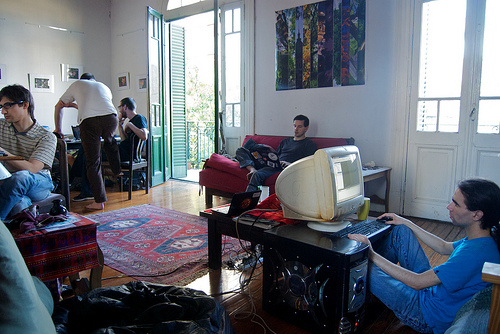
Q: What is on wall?
A: Picture.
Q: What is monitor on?
A: Wooden table.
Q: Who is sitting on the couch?
A: A man.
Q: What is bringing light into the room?
A: Windows and doors.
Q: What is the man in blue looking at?
A: A computer.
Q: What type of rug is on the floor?
A: An oriental rug.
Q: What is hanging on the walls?
A: Pictures.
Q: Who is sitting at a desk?
A: A man.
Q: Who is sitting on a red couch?
A: A man.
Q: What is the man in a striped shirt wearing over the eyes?
A: Glasses.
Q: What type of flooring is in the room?
A: Wood.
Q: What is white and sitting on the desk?
A: A computer.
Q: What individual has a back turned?
A: A man.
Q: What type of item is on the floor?
A: A rug.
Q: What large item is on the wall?
A: A poster.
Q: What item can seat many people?
A: A sofa.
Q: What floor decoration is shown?
A: A rug.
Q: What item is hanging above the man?
A: A picture.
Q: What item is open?
A: The door.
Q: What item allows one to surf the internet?
A: A computer.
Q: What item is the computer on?
A: A desk.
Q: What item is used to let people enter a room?
A: A door.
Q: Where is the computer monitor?
A: On table.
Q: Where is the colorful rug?
A: On floor.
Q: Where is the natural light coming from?
A: Windows.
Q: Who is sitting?
A: Man.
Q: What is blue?
A: Uniform.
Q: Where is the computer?
A: Desk.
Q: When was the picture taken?
A: Daytime.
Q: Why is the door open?
A: Letting air in.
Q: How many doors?
A: One.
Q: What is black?
A: Chair.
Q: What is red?
A: Couch.